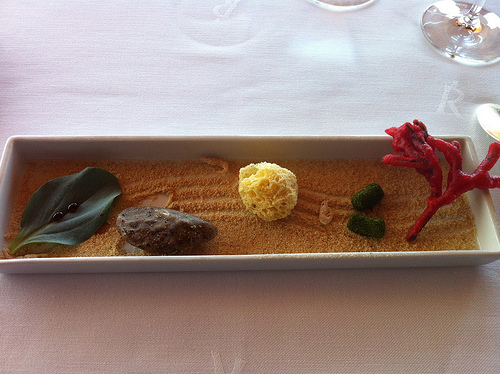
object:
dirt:
[165, 172, 217, 209]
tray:
[0, 133, 500, 274]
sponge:
[238, 161, 300, 220]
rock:
[121, 200, 227, 249]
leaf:
[8, 166, 124, 256]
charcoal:
[53, 200, 82, 221]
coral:
[382, 119, 500, 242]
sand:
[309, 169, 351, 196]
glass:
[420, 2, 500, 67]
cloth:
[94, 19, 261, 86]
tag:
[34, 32, 86, 88]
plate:
[188, 2, 269, 49]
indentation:
[170, 0, 272, 50]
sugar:
[476, 103, 500, 138]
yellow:
[252, 182, 290, 203]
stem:
[420, 199, 451, 241]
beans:
[80, 202, 121, 223]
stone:
[319, 199, 335, 225]